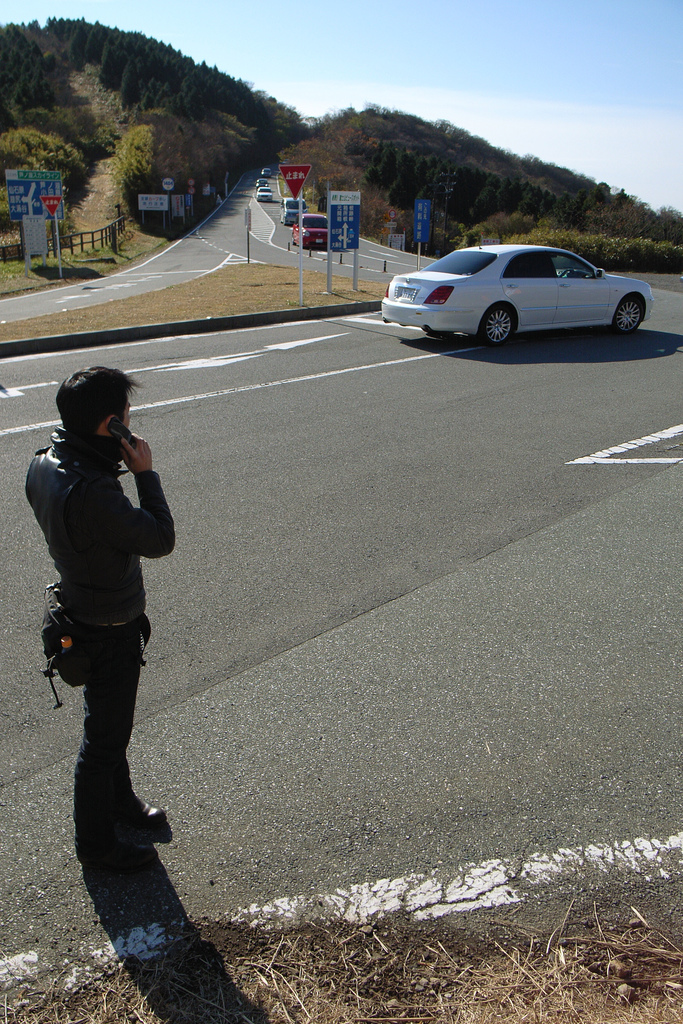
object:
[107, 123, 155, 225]
tree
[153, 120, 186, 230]
tree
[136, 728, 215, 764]
bad sentence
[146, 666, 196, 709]
bad sentence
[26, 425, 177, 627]
jacket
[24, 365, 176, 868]
person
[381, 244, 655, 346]
car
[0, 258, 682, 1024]
intersection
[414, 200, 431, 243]
sign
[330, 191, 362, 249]
sign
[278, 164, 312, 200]
sign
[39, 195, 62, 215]
sign